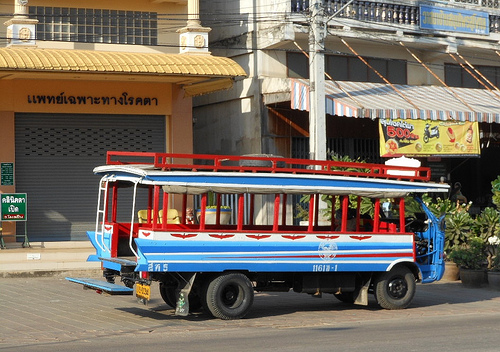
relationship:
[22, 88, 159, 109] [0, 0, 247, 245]
lettering painted on building